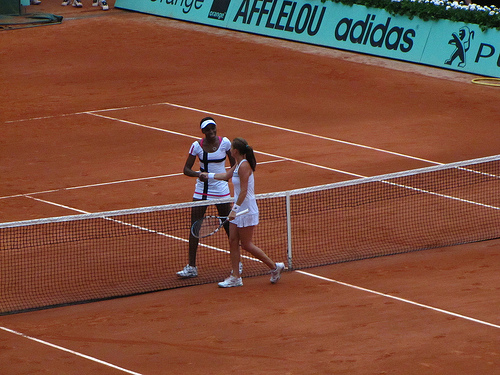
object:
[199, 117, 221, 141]
headband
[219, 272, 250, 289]
shoe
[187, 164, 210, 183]
shaking hands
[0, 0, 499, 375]
court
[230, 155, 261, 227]
tank top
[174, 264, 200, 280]
tennis sneaker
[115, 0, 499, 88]
advertisements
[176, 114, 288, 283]
athletes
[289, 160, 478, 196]
white lines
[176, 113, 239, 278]
lady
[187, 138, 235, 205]
short sleeves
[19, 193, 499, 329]
line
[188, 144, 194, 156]
stripe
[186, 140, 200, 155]
sleeve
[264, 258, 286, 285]
sneaker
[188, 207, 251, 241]
racket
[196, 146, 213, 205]
stripe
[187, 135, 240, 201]
dress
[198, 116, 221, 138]
visor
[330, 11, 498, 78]
ads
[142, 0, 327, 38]
ads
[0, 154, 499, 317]
long net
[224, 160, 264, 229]
shirt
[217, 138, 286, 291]
lady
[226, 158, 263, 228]
dress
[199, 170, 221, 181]
wristband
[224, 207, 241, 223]
left hand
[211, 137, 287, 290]
opponent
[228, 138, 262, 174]
hair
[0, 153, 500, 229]
top